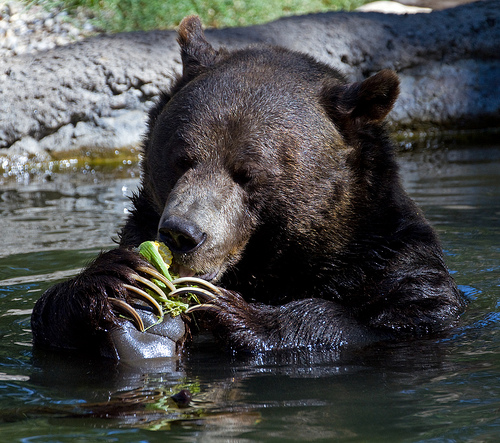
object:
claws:
[168, 276, 264, 346]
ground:
[0, 0, 500, 165]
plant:
[19, 0, 393, 36]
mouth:
[159, 244, 234, 285]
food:
[119, 240, 202, 331]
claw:
[69, 247, 175, 332]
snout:
[153, 214, 206, 252]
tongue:
[175, 265, 223, 286]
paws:
[110, 318, 183, 376]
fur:
[372, 208, 412, 266]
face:
[139, 50, 354, 288]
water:
[0, 128, 500, 443]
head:
[140, 15, 402, 291]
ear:
[342, 69, 401, 121]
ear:
[173, 14, 216, 77]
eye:
[179, 156, 195, 169]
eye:
[232, 167, 252, 185]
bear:
[28, 15, 468, 373]